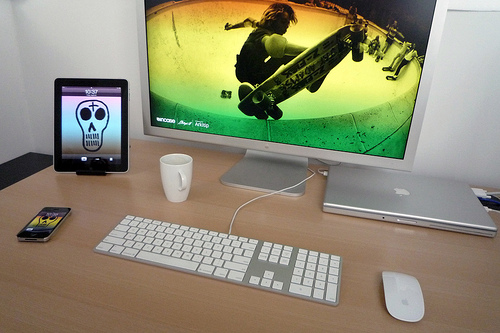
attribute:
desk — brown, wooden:
[2, 136, 498, 329]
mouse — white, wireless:
[382, 268, 425, 325]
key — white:
[250, 273, 260, 284]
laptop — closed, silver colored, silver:
[323, 162, 498, 240]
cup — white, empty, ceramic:
[160, 153, 193, 202]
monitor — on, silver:
[138, 3, 447, 170]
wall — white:
[13, 4, 498, 181]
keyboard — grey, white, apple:
[96, 214, 343, 313]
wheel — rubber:
[350, 47, 365, 62]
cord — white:
[318, 168, 329, 178]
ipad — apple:
[36, 50, 167, 232]